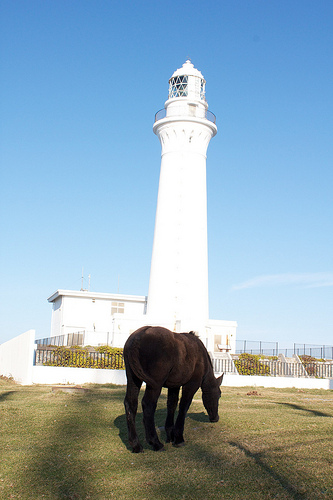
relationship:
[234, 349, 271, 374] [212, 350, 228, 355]
bush beside stairs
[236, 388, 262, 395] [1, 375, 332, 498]
poop in grass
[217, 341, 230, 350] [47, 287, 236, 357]
plaque in front of house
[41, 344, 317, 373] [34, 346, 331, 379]
bushes behind fence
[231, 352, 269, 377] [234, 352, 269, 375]
leaves on bush